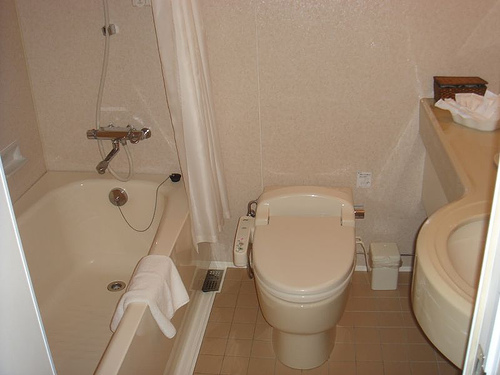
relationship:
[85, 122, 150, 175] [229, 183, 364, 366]
faucet to right of toilet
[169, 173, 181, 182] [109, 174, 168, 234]
drain plug attached by chain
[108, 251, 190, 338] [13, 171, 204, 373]
bath mat on bathtub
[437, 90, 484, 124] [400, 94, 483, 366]
dispenser on counter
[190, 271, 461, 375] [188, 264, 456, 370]
bathroom floor of tile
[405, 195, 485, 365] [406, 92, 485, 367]
sink beyond counter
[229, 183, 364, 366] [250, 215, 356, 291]
toilet with lid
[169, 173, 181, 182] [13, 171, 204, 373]
drain plug for bathtub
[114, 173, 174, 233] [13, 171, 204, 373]
chain for bathtub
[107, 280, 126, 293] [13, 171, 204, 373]
drain in bathtub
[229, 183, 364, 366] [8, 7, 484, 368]
toilet in bathroom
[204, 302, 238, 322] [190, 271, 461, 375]
tile covering bathroom floor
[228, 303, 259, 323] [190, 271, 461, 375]
tile covering bathroom floor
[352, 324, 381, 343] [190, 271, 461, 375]
tile covering bathroom floor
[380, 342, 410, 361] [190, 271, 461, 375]
tile covering bathroom floor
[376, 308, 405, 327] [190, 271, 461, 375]
tile covering bathroom floor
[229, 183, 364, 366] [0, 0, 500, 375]
toilet standing in bathroom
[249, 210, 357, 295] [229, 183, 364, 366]
lid covering toilet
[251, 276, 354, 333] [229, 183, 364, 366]
bowl belonging to toilet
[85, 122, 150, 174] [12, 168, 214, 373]
faucet mounted above bathtub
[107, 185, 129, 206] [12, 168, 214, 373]
drain control mounted on bathtub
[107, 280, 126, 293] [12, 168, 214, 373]
drain built into bathtub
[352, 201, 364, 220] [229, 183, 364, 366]
flush handle mounted on toilet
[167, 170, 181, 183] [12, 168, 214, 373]
drain plug lying on top of bathtub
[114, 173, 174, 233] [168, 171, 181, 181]
chain attached to drain plug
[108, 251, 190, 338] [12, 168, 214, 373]
bath mat folded on top of bathtub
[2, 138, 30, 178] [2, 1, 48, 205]
soap holder built into wall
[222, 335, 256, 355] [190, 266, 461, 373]
tile covering bathroom floor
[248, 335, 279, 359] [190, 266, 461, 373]
tile covering bathroom floor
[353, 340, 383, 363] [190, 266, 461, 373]
tile covering bathroom floor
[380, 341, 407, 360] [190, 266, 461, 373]
tile covering bathroom floor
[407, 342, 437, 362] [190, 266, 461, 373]
tile covering bathroom floor